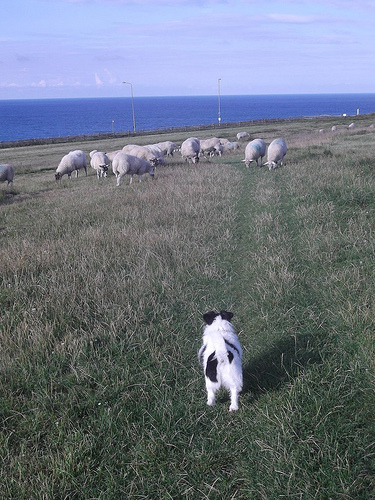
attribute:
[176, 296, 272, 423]
dog — black, white, herding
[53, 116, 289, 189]
sheep — grazing, white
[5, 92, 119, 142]
water — blue, calm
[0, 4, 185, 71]
sky — blue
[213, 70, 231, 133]
light — tall